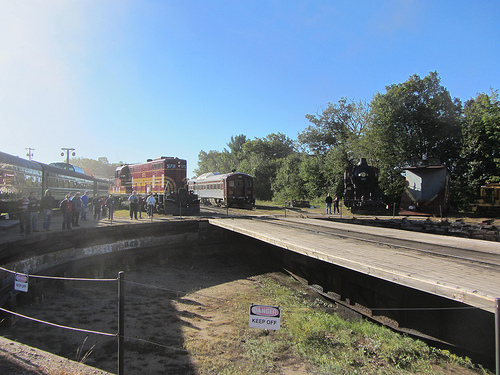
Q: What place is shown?
A: It is a station.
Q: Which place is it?
A: It is a station.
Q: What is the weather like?
A: It is clear.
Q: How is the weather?
A: It is clear.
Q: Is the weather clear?
A: Yes, it is clear.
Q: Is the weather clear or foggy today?
A: It is clear.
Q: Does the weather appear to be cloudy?
A: No, it is clear.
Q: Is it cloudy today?
A: No, it is clear.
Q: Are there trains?
A: Yes, there is a train.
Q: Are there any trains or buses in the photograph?
A: Yes, there is a train.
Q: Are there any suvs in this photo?
A: No, there are no suvs.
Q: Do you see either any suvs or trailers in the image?
A: No, there are no suvs or trailers.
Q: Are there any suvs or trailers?
A: No, there are no suvs or trailers.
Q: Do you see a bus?
A: No, there are no buses.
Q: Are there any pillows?
A: No, there are no pillows.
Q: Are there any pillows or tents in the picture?
A: No, there are no pillows or tents.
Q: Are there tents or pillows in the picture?
A: No, there are no pillows or tents.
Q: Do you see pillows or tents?
A: No, there are no pillows or tents.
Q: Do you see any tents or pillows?
A: No, there are no pillows or tents.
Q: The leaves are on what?
A: The leaves are on the tree.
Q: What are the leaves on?
A: The leaves are on the tree.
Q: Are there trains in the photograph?
A: Yes, there is a train.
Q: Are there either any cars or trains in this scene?
A: Yes, there is a train.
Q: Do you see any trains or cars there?
A: Yes, there is a train.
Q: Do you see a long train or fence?
A: Yes, there is a long train.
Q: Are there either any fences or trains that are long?
A: Yes, the train is long.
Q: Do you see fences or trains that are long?
A: Yes, the train is long.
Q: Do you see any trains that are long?
A: Yes, there is a long train.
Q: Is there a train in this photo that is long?
A: Yes, there is a train that is long.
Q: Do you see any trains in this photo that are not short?
A: Yes, there is a long train.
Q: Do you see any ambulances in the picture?
A: No, there are no ambulances.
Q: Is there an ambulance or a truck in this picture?
A: No, there are no ambulances or trucks.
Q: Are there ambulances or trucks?
A: No, there are no ambulances or trucks.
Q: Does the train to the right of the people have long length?
A: Yes, the train is long.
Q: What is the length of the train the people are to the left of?
A: The train is long.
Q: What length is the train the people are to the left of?
A: The train is long.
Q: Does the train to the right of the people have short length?
A: No, the train is long.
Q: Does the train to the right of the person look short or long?
A: The train is long.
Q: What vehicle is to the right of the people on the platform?
A: The vehicle is a train.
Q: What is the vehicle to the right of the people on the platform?
A: The vehicle is a train.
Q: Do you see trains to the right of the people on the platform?
A: Yes, there is a train to the right of the people.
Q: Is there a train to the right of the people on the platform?
A: Yes, there is a train to the right of the people.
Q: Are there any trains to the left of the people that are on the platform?
A: No, the train is to the right of the people.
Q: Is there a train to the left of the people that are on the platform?
A: No, the train is to the right of the people.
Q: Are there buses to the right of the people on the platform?
A: No, there is a train to the right of the people.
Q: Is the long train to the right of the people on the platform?
A: Yes, the train is to the right of the people.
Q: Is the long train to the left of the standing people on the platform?
A: No, the train is to the right of the people.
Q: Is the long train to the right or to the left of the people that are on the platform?
A: The train is to the right of the people.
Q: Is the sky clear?
A: Yes, the sky is clear.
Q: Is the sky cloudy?
A: No, the sky is clear.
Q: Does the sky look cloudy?
A: No, the sky is clear.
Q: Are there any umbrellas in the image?
A: No, there are no umbrellas.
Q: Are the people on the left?
A: Yes, the people are on the left of the image.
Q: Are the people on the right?
A: No, the people are on the left of the image.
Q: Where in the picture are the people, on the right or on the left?
A: The people are on the left of the image.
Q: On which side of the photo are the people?
A: The people are on the left of the image.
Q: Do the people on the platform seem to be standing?
A: Yes, the people are standing.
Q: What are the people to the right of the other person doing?
A: The people are standing.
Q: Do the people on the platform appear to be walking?
A: No, the people are standing.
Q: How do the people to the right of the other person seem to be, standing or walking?
A: The people are standing.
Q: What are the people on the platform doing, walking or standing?
A: The people are standing.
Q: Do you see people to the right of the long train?
A: No, the people are to the left of the train.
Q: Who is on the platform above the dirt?
A: The people are on the platform.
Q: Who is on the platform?
A: The people are on the platform.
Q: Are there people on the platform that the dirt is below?
A: Yes, there are people on the platform.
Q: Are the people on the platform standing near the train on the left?
A: Yes, the people are standing near the train.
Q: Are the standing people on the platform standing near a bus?
A: No, the people are standing near the train.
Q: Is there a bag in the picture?
A: No, there are no bags.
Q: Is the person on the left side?
A: Yes, the person is on the left of the image.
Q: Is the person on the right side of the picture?
A: No, the person is on the left of the image.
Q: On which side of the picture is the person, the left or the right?
A: The person is on the left of the image.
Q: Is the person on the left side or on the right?
A: The person is on the left of the image.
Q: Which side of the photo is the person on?
A: The person is on the left of the image.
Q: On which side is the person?
A: The person is on the left of the image.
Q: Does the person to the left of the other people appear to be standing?
A: Yes, the person is standing.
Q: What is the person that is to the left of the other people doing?
A: The person is standing.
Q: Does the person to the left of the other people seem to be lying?
A: No, the person is standing.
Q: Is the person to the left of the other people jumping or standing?
A: The person is standing.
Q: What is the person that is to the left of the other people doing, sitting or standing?
A: The person is standing.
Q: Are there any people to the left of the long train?
A: Yes, there is a person to the left of the train.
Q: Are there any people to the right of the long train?
A: No, the person is to the left of the train.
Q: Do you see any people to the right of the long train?
A: No, the person is to the left of the train.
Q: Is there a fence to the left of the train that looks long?
A: No, there is a person to the left of the train.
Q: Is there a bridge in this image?
A: Yes, there is a bridge.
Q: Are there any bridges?
A: Yes, there is a bridge.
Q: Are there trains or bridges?
A: Yes, there is a bridge.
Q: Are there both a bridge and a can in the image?
A: No, there is a bridge but no cans.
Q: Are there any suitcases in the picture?
A: No, there are no suitcases.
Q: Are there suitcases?
A: No, there are no suitcases.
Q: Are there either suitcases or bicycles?
A: No, there are no suitcases or bicycles.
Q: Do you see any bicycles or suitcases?
A: No, there are no suitcases or bicycles.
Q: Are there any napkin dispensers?
A: No, there are no napkin dispensers.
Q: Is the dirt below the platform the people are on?
A: Yes, the dirt is below the platform.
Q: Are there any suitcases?
A: No, there are no suitcases.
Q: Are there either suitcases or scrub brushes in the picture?
A: No, there are no suitcases or scrub brushes.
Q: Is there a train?
A: Yes, there is a train.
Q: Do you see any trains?
A: Yes, there is a train.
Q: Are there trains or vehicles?
A: Yes, there is a train.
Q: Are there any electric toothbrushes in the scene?
A: No, there are no electric toothbrushes.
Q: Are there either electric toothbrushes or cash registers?
A: No, there are no electric toothbrushes or cash registers.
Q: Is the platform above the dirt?
A: Yes, the platform is above the dirt.